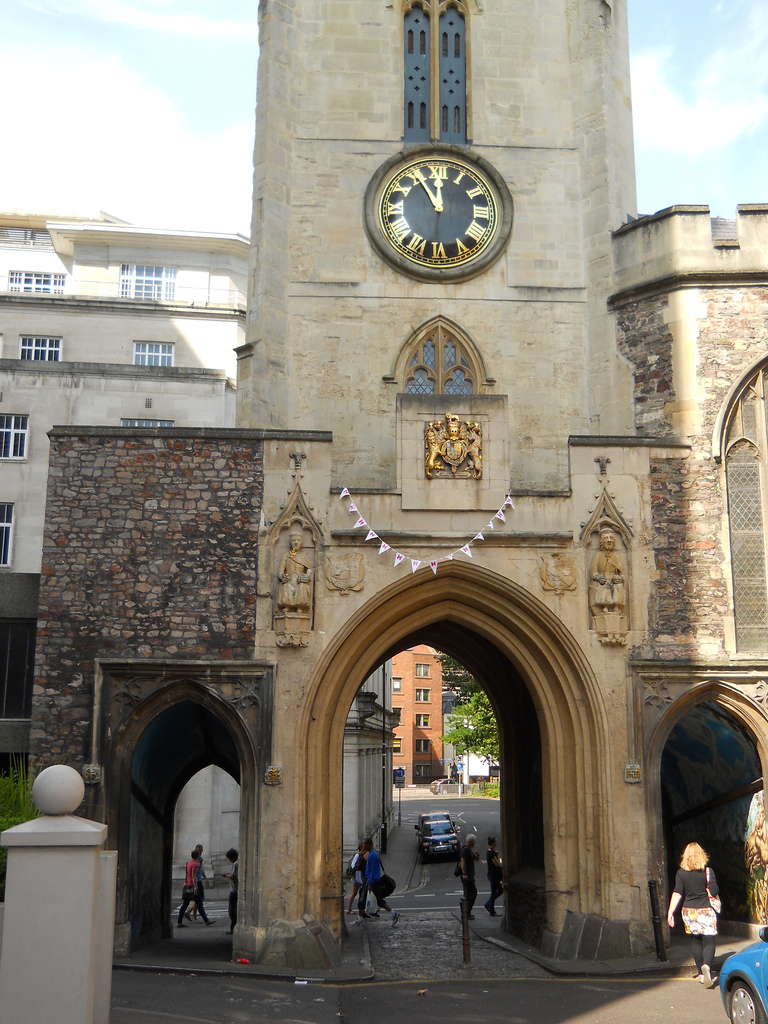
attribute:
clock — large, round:
[356, 152, 526, 297]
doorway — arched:
[298, 558, 613, 955]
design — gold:
[420, 411, 487, 482]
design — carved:
[579, 453, 640, 648]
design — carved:
[266, 446, 327, 647]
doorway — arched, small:
[100, 676, 263, 959]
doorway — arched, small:
[642, 676, 767, 945]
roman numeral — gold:
[427, 157, 450, 180]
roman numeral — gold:
[449, 164, 471, 186]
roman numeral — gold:
[463, 182, 488, 200]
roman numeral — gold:
[468, 203, 491, 221]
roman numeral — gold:
[466, 217, 489, 244]